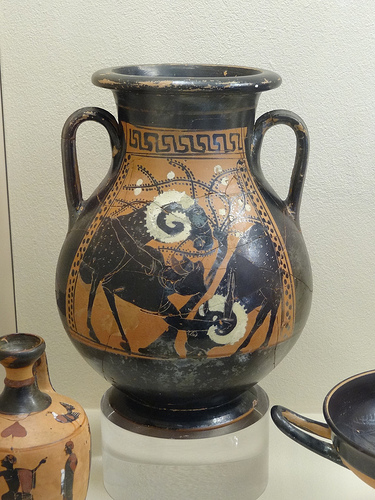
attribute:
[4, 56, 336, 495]
vase — old, ethnic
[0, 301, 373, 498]
shelf — white, display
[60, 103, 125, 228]
handle — brown 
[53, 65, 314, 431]
vase — pretty, black, brown, old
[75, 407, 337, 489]
countertop — white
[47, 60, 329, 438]
pot — brown 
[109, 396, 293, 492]
stand — white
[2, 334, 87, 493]
vase — black, brown, small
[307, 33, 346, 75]
wall — white 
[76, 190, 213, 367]
ram — drawing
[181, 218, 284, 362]
ram — drawing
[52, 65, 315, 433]
pottery — old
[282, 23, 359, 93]
wall — white 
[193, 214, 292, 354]
ram — black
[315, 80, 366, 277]
wall — white, textured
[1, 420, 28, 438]
spades — Red 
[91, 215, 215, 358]
bull — black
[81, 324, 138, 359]
bull hooves — black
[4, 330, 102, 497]
vase — old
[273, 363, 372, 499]
vase — old